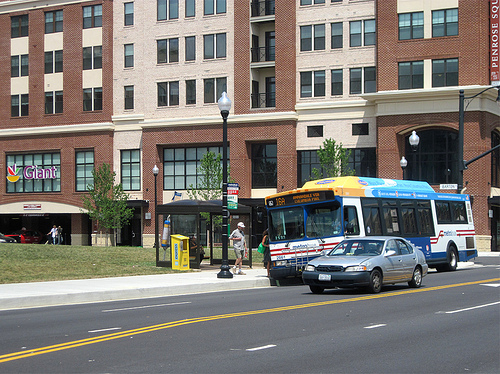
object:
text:
[470, 43, 475, 48]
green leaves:
[112, 180, 124, 201]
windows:
[360, 65, 377, 95]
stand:
[170, 232, 192, 273]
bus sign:
[226, 179, 239, 212]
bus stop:
[153, 194, 254, 270]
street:
[0, 255, 499, 373]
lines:
[242, 338, 280, 355]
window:
[50, 176, 65, 193]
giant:
[18, 160, 58, 182]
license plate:
[316, 273, 332, 281]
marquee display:
[266, 191, 324, 207]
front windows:
[266, 200, 338, 241]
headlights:
[303, 264, 318, 273]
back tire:
[407, 266, 425, 290]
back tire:
[436, 242, 458, 273]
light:
[216, 91, 234, 113]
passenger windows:
[355, 200, 384, 235]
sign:
[3, 156, 58, 185]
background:
[1, 0, 499, 373]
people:
[44, 224, 61, 246]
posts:
[210, 108, 239, 277]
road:
[0, 255, 499, 373]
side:
[3, 267, 266, 314]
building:
[0, 18, 499, 258]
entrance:
[0, 207, 72, 246]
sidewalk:
[0, 266, 268, 314]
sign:
[487, 3, 499, 90]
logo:
[3, 163, 20, 184]